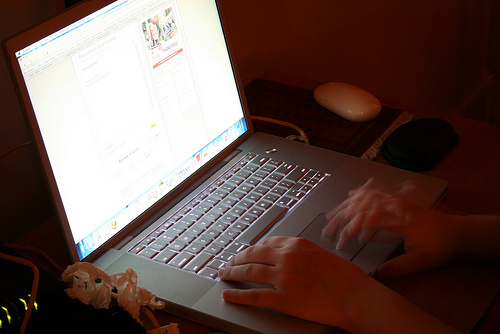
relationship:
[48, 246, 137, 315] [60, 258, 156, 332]
tissue on side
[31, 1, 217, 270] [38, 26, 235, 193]
website on computer screen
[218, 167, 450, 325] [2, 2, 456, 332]
hands on computer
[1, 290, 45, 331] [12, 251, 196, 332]
lights on table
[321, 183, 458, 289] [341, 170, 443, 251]
hand in motion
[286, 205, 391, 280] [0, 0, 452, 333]
mouse pad on computer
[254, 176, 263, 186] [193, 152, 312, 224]
key on keyboard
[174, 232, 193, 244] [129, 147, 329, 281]
silver key on keyboard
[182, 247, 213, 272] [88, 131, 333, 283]
key on keyboard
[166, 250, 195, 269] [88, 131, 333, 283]
key on keyboard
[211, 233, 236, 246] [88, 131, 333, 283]
key on keyboard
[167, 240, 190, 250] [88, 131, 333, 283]
key on keyboard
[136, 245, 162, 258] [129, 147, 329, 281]
key on keyboard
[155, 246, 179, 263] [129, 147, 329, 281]
key on keyboard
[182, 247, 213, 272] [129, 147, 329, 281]
key on keyboard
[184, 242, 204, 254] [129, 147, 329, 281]
key on keyboard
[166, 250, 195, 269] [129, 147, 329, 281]
key on keyboard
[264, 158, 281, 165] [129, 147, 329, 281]
keys on keyboard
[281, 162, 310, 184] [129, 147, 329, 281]
keys on keyboard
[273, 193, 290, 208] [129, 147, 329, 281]
keys on keyboard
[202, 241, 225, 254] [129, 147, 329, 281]
key on keyboard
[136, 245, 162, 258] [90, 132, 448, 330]
key on keyboard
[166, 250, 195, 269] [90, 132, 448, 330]
key on keyboard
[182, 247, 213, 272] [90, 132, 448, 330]
key on keyboard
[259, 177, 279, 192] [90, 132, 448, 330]
key on keyboard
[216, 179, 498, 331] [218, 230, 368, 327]
person has hand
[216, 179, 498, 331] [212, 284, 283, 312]
person has pinky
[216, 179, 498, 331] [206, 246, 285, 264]
person has middle finger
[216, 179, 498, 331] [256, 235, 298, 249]
person has finger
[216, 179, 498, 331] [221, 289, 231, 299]
person has fingernail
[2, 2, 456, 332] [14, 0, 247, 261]
computer has computer screen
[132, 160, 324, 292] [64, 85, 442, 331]
keyboard on desk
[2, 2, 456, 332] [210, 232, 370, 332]
computer near hand